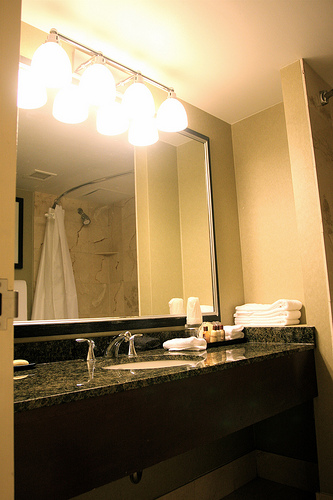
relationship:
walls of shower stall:
[44, 184, 142, 325] [27, 185, 176, 317]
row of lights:
[27, 14, 198, 141] [36, 48, 212, 145]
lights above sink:
[36, 48, 212, 145] [47, 296, 203, 380]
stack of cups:
[178, 288, 207, 329] [161, 277, 233, 341]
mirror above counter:
[3, 119, 218, 324] [0, 309, 324, 420]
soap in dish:
[10, 347, 39, 368] [10, 353, 52, 377]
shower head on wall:
[76, 198, 97, 231] [65, 199, 134, 309]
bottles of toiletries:
[205, 322, 232, 345] [198, 326, 236, 343]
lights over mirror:
[27, 14, 198, 141] [3, 119, 218, 324]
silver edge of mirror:
[195, 127, 226, 307] [3, 119, 218, 324]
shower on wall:
[67, 197, 115, 290] [65, 199, 134, 309]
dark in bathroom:
[154, 371, 322, 498] [5, 45, 314, 498]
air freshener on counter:
[186, 293, 203, 331] [0, 309, 324, 420]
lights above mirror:
[27, 14, 198, 141] [3, 119, 218, 324]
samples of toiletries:
[199, 315, 227, 347] [198, 326, 236, 343]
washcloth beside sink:
[158, 332, 213, 355] [104, 339, 208, 377]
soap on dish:
[10, 347, 39, 368] [10, 353, 52, 377]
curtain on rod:
[36, 206, 80, 321] [47, 157, 135, 212]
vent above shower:
[18, 161, 69, 186] [67, 197, 115, 290]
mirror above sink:
[3, 119, 218, 324] [104, 339, 208, 377]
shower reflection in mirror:
[67, 197, 115, 290] [3, 119, 218, 324]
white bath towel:
[223, 287, 307, 325] [232, 295, 307, 334]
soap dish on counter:
[10, 353, 52, 377] [0, 309, 324, 420]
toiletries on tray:
[198, 326, 236, 343] [204, 331, 259, 352]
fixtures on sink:
[60, 323, 160, 365] [104, 339, 208, 377]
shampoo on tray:
[199, 315, 227, 347] [204, 331, 259, 352]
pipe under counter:
[125, 467, 185, 492] [0, 309, 324, 420]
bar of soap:
[12, 356, 41, 369] [10, 347, 39, 368]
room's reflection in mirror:
[5, 45, 314, 498] [3, 119, 218, 324]